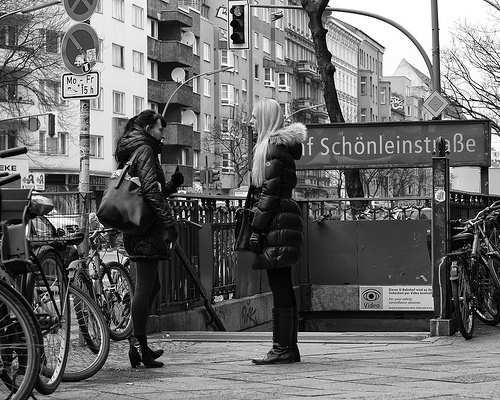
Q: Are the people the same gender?
A: Yes, all the people are female.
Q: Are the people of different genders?
A: No, all the people are female.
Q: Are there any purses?
A: Yes, there is a purse.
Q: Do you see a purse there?
A: Yes, there is a purse.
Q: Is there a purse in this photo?
A: Yes, there is a purse.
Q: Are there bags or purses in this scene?
A: Yes, there is a purse.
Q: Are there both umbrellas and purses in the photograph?
A: No, there is a purse but no umbrellas.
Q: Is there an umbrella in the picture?
A: No, there are no umbrellas.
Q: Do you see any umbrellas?
A: No, there are no umbrellas.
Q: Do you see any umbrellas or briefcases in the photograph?
A: No, there are no umbrellas or briefcases.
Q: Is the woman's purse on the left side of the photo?
A: Yes, the purse is on the left of the image.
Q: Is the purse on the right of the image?
A: No, the purse is on the left of the image.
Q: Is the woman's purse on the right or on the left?
A: The purse is on the left of the image.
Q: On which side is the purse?
A: The purse is on the left of the image.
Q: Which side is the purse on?
A: The purse is on the left of the image.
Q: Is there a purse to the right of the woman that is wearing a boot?
A: No, the purse is to the left of the woman.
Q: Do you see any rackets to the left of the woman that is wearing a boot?
A: No, there is a purse to the left of the woman.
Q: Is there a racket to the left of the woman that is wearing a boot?
A: No, there is a purse to the left of the woman.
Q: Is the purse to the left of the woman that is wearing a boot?
A: Yes, the purse is to the left of the woman.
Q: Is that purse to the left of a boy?
A: No, the purse is to the left of the woman.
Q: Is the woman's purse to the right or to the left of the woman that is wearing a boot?
A: The purse is to the left of the woman.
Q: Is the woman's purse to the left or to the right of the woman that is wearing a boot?
A: The purse is to the left of the woman.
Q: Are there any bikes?
A: Yes, there are bikes.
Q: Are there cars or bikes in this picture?
A: Yes, there are bikes.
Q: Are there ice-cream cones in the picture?
A: No, there are no ice-cream cones.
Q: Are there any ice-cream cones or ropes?
A: No, there are no ice-cream cones or ropes.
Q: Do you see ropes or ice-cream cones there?
A: No, there are no ice-cream cones or ropes.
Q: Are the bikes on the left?
A: Yes, the bikes are on the left of the image.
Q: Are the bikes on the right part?
A: No, the bikes are on the left of the image.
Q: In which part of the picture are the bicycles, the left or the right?
A: The bicycles are on the left of the image.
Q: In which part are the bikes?
A: The bikes are on the left of the image.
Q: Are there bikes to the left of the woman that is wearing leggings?
A: Yes, there are bikes to the left of the woman.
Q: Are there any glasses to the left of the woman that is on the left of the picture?
A: No, there are bikes to the left of the woman.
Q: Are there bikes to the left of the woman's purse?
A: Yes, there are bikes to the left of the purse.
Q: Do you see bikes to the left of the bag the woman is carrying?
A: Yes, there are bikes to the left of the purse.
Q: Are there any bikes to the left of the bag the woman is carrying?
A: Yes, there are bikes to the left of the purse.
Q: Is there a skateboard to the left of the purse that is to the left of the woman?
A: No, there are bikes to the left of the purse.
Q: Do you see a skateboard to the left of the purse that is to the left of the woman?
A: No, there are bikes to the left of the purse.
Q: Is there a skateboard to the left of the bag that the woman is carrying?
A: No, there are bikes to the left of the purse.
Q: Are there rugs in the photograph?
A: No, there are no rugs.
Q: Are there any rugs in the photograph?
A: No, there are no rugs.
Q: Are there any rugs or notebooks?
A: No, there are no rugs or notebooks.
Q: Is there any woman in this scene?
A: Yes, there is a woman.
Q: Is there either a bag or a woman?
A: Yes, there is a woman.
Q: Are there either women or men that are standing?
A: Yes, the woman is standing.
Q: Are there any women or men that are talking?
A: Yes, the woman is talking.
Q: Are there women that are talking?
A: Yes, there is a woman that is talking.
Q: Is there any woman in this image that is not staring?
A: Yes, there is a woman that is talking.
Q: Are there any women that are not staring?
A: Yes, there is a woman that is talking.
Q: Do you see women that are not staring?
A: Yes, there is a woman that is talking .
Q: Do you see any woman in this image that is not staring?
A: Yes, there is a woman that is talking .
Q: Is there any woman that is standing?
A: Yes, there is a woman that is standing.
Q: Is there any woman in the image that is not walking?
A: Yes, there is a woman that is standing.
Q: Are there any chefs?
A: No, there are no chefs.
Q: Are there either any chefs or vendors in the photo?
A: No, there are no chefs or vendors.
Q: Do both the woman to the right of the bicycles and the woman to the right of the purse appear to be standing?
A: Yes, both the woman and the woman are standing.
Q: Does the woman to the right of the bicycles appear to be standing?
A: Yes, the woman is standing.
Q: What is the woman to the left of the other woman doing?
A: The woman is standing.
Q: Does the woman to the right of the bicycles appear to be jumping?
A: No, the woman is standing.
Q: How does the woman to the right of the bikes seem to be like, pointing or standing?
A: The woman is standing.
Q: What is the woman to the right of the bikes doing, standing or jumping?
A: The woman is standing.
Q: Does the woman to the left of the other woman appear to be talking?
A: Yes, the woman is talking.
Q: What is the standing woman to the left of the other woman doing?
A: The woman is talking.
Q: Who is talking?
A: The woman is talking.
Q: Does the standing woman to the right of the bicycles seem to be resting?
A: No, the woman is talking.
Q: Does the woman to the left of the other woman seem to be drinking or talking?
A: The woman is talking.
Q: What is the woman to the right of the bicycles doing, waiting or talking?
A: The woman is talking.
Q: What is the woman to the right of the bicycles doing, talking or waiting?
A: The woman is talking.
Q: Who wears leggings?
A: The woman wears leggings.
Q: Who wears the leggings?
A: The woman wears leggings.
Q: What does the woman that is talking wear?
A: The woman wears leggings.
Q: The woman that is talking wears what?
A: The woman wears leggings.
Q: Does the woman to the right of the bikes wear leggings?
A: Yes, the woman wears leggings.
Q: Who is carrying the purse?
A: The woman is carrying the purse.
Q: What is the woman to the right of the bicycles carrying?
A: The woman is carrying a purse.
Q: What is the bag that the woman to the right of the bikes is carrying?
A: The bag is a purse.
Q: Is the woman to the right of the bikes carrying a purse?
A: Yes, the woman is carrying a purse.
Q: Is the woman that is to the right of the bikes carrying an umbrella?
A: No, the woman is carrying a purse.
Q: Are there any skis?
A: No, there are no skis.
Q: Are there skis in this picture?
A: No, there are no skis.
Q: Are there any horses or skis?
A: No, there are no skis or horses.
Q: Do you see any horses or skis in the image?
A: No, there are no skis or horses.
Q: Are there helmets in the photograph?
A: No, there are no helmets.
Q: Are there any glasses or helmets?
A: No, there are no helmets or glasses.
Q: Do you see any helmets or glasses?
A: No, there are no helmets or glasses.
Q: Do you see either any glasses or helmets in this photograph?
A: No, there are no helmets or glasses.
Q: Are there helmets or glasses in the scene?
A: No, there are no helmets or glasses.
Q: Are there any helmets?
A: No, there are no helmets.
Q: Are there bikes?
A: Yes, there is a bike.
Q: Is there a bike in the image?
A: Yes, there is a bike.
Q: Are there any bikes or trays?
A: Yes, there is a bike.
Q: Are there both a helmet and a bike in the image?
A: No, there is a bike but no helmets.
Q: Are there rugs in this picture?
A: No, there are no rugs.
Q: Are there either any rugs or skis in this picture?
A: No, there are no rugs or skis.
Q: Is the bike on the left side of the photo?
A: Yes, the bike is on the left of the image.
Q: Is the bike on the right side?
A: No, the bike is on the left of the image.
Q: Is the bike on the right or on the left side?
A: The bike is on the left of the image.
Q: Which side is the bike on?
A: The bike is on the left of the image.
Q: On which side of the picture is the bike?
A: The bike is on the left of the image.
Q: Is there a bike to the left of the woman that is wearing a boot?
A: Yes, there is a bike to the left of the woman.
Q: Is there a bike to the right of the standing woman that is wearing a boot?
A: No, the bike is to the left of the woman.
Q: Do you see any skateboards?
A: No, there are no skateboards.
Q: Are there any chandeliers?
A: No, there are no chandeliers.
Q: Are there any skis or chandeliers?
A: No, there are no chandeliers or skis.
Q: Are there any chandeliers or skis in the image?
A: No, there are no chandeliers or skis.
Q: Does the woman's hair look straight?
A: Yes, the hair is straight.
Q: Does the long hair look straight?
A: Yes, the hair is straight.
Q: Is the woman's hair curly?
A: No, the hair is straight.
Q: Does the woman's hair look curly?
A: No, the hair is straight.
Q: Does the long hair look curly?
A: No, the hair is straight.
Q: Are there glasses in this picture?
A: No, there are no glasses.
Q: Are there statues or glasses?
A: No, there are no glasses or statues.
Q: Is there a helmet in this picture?
A: No, there are no helmets.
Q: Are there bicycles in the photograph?
A: Yes, there is a bicycle.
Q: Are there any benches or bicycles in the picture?
A: Yes, there is a bicycle.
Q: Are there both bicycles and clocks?
A: No, there is a bicycle but no clocks.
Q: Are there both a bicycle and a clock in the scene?
A: No, there is a bicycle but no clocks.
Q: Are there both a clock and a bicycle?
A: No, there is a bicycle but no clocks.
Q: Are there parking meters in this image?
A: No, there are no parking meters.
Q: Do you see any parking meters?
A: No, there are no parking meters.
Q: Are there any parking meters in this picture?
A: No, there are no parking meters.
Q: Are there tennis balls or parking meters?
A: No, there are no parking meters or tennis balls.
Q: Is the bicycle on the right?
A: Yes, the bicycle is on the right of the image.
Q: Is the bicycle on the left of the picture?
A: No, the bicycle is on the right of the image.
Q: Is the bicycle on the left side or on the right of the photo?
A: The bicycle is on the right of the image.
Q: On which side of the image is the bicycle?
A: The bicycle is on the right of the image.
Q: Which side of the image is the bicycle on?
A: The bicycle is on the right of the image.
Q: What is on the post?
A: The sign is on the post.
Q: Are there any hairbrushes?
A: No, there are no hairbrushes.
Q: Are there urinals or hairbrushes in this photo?
A: No, there are no hairbrushes or urinals.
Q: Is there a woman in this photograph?
A: Yes, there is a woman.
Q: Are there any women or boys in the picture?
A: Yes, there is a woman.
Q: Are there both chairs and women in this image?
A: No, there is a woman but no chairs.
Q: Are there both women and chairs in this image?
A: No, there is a woman but no chairs.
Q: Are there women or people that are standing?
A: Yes, the woman is standing.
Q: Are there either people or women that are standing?
A: Yes, the woman is standing.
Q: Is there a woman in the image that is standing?
A: Yes, there is a woman that is standing.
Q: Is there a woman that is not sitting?
A: Yes, there is a woman that is standing.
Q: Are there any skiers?
A: No, there are no skiers.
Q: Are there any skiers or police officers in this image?
A: No, there are no skiers or police officers.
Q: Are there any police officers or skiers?
A: No, there are no skiers or police officers.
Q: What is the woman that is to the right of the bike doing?
A: The woman is standing.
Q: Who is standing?
A: The woman is standing.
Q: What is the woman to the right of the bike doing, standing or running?
A: The woman is standing.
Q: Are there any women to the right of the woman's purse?
A: Yes, there is a woman to the right of the purse.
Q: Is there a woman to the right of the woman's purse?
A: Yes, there is a woman to the right of the purse.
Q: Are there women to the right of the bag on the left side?
A: Yes, there is a woman to the right of the purse.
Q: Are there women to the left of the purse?
A: No, the woman is to the right of the purse.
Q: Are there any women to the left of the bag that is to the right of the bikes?
A: No, the woman is to the right of the purse.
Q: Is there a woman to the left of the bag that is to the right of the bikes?
A: No, the woman is to the right of the purse.